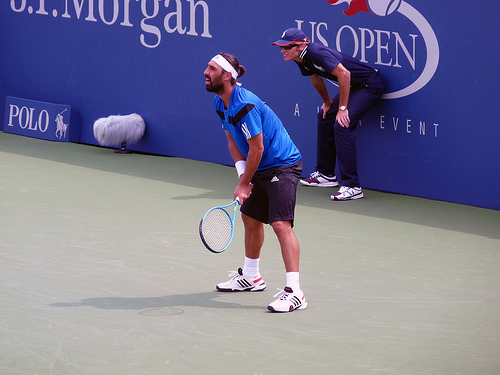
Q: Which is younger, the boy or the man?
A: The boy is younger than the man.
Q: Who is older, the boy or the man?
A: The man is older than the boy.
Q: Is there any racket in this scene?
A: Yes, there is a racket.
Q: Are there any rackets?
A: Yes, there is a racket.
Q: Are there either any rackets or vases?
A: Yes, there is a racket.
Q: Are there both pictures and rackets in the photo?
A: No, there is a racket but no pictures.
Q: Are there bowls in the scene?
A: No, there are no bowls.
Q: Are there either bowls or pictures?
A: No, there are no bowls or pictures.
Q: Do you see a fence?
A: No, there are no fences.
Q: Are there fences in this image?
A: No, there are no fences.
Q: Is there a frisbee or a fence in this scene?
A: No, there are no fences or frisbees.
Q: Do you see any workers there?
A: No, there are no workers.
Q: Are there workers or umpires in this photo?
A: No, there are no workers or umpires.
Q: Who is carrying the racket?
A: The man is carrying the racket.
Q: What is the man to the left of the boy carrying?
A: The man is carrying a racket.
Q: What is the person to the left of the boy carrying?
A: The man is carrying a racket.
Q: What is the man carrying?
A: The man is carrying a racket.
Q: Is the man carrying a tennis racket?
A: Yes, the man is carrying a tennis racket.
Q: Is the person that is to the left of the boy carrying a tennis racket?
A: Yes, the man is carrying a tennis racket.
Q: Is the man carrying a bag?
A: No, the man is carrying a tennis racket.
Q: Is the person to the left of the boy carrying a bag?
A: No, the man is carrying a tennis racket.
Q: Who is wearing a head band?
A: The man is wearing a head band.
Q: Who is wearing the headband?
A: The man is wearing a head band.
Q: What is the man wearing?
A: The man is wearing a headband.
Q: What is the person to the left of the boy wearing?
A: The man is wearing a headband.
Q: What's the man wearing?
A: The man is wearing a headband.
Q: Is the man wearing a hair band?
A: Yes, the man is wearing a hair band.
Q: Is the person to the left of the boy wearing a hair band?
A: Yes, the man is wearing a hair band.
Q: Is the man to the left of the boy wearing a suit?
A: No, the man is wearing a hair band.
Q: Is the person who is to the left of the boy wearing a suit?
A: No, the man is wearing a hair band.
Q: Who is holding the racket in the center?
A: The man is holding the tennis racket.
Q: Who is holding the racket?
A: The man is holding the tennis racket.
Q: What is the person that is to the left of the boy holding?
A: The man is holding the racket.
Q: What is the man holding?
A: The man is holding the racket.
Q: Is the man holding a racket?
A: Yes, the man is holding a racket.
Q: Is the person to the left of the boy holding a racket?
A: Yes, the man is holding a racket.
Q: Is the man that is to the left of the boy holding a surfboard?
A: No, the man is holding a racket.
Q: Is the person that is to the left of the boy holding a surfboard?
A: No, the man is holding a racket.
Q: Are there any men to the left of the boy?
A: Yes, there is a man to the left of the boy.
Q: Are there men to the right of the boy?
A: No, the man is to the left of the boy.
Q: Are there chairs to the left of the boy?
A: No, there is a man to the left of the boy.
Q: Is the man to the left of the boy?
A: Yes, the man is to the left of the boy.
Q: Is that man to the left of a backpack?
A: No, the man is to the left of the boy.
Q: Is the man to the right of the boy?
A: No, the man is to the left of the boy.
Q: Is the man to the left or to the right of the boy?
A: The man is to the left of the boy.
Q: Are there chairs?
A: No, there are no chairs.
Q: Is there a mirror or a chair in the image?
A: No, there are no chairs or mirrors.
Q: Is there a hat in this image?
A: Yes, there is a hat.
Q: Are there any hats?
A: Yes, there is a hat.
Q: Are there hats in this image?
A: Yes, there is a hat.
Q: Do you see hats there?
A: Yes, there is a hat.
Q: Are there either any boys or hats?
A: Yes, there is a hat.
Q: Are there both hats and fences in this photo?
A: No, there is a hat but no fences.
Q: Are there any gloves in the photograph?
A: No, there are no gloves.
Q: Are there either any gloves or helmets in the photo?
A: No, there are no gloves or helmets.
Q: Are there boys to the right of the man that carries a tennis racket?
A: Yes, there is a boy to the right of the man.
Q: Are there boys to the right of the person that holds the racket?
A: Yes, there is a boy to the right of the man.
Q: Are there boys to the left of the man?
A: No, the boy is to the right of the man.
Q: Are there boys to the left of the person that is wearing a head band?
A: No, the boy is to the right of the man.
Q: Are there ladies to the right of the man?
A: No, there is a boy to the right of the man.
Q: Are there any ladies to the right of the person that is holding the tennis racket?
A: No, there is a boy to the right of the man.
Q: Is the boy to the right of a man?
A: Yes, the boy is to the right of a man.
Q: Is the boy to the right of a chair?
A: No, the boy is to the right of a man.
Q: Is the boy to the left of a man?
A: No, the boy is to the right of a man.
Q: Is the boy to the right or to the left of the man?
A: The boy is to the right of the man.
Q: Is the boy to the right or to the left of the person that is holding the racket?
A: The boy is to the right of the man.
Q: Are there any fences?
A: No, there are no fences.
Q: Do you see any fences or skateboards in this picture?
A: No, there are no fences or skateboards.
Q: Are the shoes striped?
A: Yes, the shoes are striped.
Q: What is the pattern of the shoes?
A: The shoes are striped.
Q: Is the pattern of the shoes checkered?
A: No, the shoes are striped.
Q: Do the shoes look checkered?
A: No, the shoes are striped.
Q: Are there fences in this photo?
A: No, there are no fences.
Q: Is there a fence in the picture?
A: No, there are no fences.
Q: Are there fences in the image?
A: No, there are no fences.